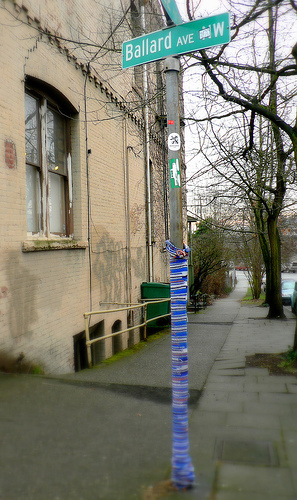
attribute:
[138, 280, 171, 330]
cans — green, plastic, garbage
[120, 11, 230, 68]
sign — white, green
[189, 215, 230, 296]
bushes — small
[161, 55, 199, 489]
pole — metal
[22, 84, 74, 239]
window — large, pane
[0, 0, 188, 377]
building — brick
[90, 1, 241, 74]
street signs — green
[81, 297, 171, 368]
fence — small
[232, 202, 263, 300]
tree — old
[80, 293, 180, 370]
railing — yellow, metal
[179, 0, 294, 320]
tree — very tall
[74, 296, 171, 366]
railing — cream, metal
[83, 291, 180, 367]
fence — metal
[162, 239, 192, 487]
pole — knit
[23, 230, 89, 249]
sill — window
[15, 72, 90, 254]
window — chipped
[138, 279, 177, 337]
trashbin — green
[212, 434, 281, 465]
plate — square, metal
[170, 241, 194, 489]
stocking — blue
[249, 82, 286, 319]
trees — small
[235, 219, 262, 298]
trees — small